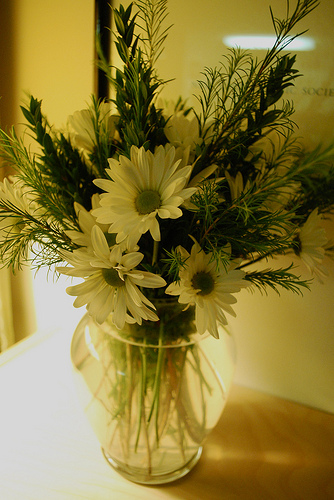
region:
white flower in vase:
[91, 134, 193, 240]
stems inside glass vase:
[109, 335, 209, 463]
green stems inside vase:
[133, 349, 171, 439]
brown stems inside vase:
[161, 354, 184, 404]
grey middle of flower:
[130, 186, 160, 216]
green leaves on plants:
[250, 261, 302, 301]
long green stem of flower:
[255, 200, 304, 273]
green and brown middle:
[138, 192, 153, 210]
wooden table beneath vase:
[221, 414, 298, 483]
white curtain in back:
[0, 268, 34, 345]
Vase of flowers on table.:
[0, 0, 331, 486]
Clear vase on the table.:
[61, 283, 246, 488]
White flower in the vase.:
[164, 242, 252, 337]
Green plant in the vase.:
[245, 259, 313, 308]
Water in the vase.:
[64, 317, 237, 488]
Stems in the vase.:
[74, 329, 230, 476]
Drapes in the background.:
[0, 234, 41, 352]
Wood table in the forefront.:
[0, 315, 328, 498]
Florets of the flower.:
[132, 183, 164, 214]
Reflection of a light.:
[217, 28, 322, 56]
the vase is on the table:
[14, 197, 281, 482]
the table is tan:
[229, 379, 314, 489]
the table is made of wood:
[229, 380, 322, 488]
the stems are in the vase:
[84, 315, 226, 472]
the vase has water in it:
[62, 290, 233, 482]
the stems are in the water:
[79, 309, 235, 463]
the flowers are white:
[51, 110, 266, 353]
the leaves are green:
[96, 26, 298, 295]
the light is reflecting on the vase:
[56, 317, 137, 398]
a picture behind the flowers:
[113, 0, 322, 264]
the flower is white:
[88, 146, 194, 251]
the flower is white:
[83, 136, 184, 246]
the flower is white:
[73, 145, 205, 261]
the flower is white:
[75, 146, 209, 249]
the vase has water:
[62, 292, 230, 487]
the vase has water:
[70, 306, 215, 465]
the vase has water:
[76, 320, 229, 491]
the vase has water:
[77, 313, 210, 470]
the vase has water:
[67, 323, 206, 491]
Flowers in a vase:
[9, 26, 315, 493]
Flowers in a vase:
[11, 18, 321, 487]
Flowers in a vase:
[10, 28, 333, 492]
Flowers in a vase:
[14, 37, 332, 490]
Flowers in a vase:
[13, 11, 328, 491]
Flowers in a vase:
[13, 15, 327, 495]